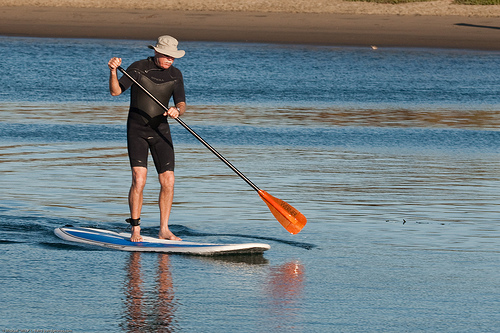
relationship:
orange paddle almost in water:
[111, 62, 307, 235] [270, 104, 497, 259]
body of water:
[2, 37, 497, 331] [12, 30, 498, 327]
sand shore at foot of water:
[0, 0, 500, 52] [12, 30, 498, 327]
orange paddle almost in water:
[111, 62, 307, 235] [28, 49, 455, 309]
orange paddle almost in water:
[111, 62, 307, 235] [215, 114, 450, 308]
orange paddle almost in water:
[111, 62, 307, 235] [347, 50, 484, 329]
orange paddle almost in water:
[197, 144, 315, 245] [7, 50, 455, 326]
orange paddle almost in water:
[111, 62, 307, 235] [0, 3, 497, 331]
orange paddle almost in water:
[111, 62, 307, 235] [12, 30, 498, 327]